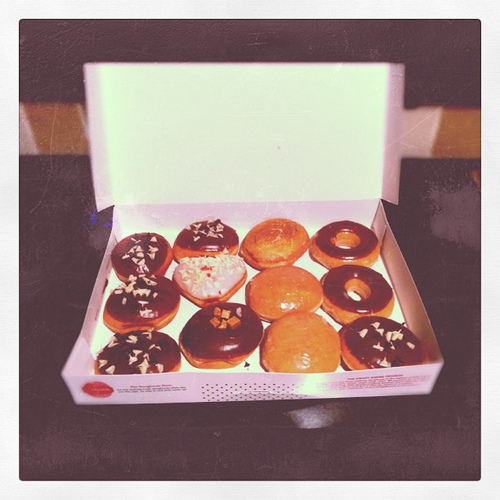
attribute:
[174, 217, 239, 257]
donut — round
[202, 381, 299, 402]
dots — black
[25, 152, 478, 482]
countertop — black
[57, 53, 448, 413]
box — donut